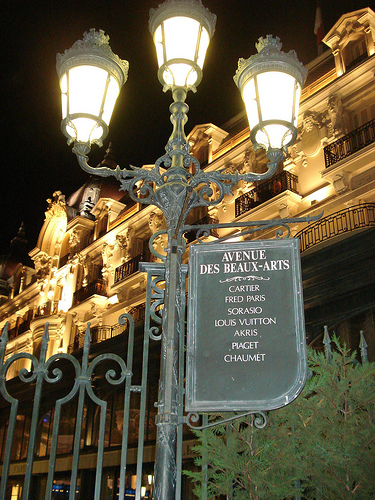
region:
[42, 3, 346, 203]
Lights on the pole.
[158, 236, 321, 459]
sign on the pole.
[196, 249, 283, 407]
Words written on sign.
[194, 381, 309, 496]
Bush behind the sign.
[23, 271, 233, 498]
Fence in front of the building.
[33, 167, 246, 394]
Building behind the fence.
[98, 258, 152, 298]
Balcony on the building.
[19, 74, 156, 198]
Sky behind the lights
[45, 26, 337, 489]
A lamp post with lights.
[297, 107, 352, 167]
Details on the building.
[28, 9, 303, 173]
three glowing street lamps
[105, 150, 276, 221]
ornamental black lamp pole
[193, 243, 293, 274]
words written in french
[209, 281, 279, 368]
list of names on sign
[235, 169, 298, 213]
black railing on balcony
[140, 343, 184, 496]
pole under three lamps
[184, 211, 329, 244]
bar holding up sign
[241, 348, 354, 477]
tree in front of fence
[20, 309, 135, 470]
metal rails on fence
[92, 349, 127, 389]
curly metal on fence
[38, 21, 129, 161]
lamp decorated with metal crown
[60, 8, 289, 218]
lamppost supporting three lit lights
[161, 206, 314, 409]
sign naming avenue with list of high-end companies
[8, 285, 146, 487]
gate forged with straight and curved metal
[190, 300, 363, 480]
evergreen branches covering fence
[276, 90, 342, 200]
facade decorated with garlands, faces and carvings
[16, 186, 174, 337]
building glowing in white and gold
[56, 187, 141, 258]
architectural windows extending from roof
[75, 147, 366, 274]
terraces with black railings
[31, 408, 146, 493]
blue lights glowing from within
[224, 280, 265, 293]
This is the word Cartier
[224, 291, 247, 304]
This is the word Fred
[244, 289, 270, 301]
This is the word PARIS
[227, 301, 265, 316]
This is the word SORASIO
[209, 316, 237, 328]
This is the word LOUIS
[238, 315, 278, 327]
This is the word VUITTON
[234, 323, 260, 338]
This is the word AKRIS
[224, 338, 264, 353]
This is the word PIAGET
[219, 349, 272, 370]
This is the word CHAUMET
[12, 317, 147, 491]
This is a metal gate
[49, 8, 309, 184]
these lights are on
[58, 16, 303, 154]
the lights are yellow in color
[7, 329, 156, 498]
this is a metallic fence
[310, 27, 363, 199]
this is a house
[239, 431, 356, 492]
the trees are green in color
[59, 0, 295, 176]
the lights are three in number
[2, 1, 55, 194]
the sky is dark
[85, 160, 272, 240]
the stand is metallic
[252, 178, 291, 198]
the balcon is black in color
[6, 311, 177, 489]
the fence is green in color